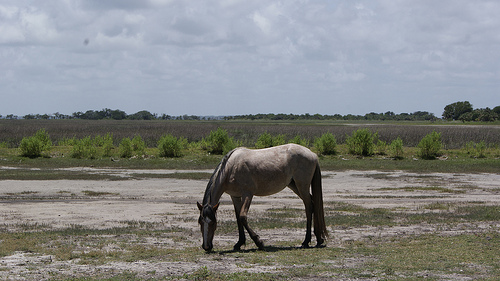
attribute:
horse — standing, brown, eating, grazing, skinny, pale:
[196, 144, 328, 252]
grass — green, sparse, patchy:
[37, 146, 460, 175]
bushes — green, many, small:
[17, 132, 445, 156]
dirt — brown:
[119, 171, 411, 244]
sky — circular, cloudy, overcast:
[49, 9, 403, 100]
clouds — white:
[166, 20, 284, 63]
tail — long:
[310, 168, 335, 246]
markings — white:
[203, 222, 207, 240]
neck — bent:
[206, 175, 221, 212]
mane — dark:
[213, 160, 223, 206]